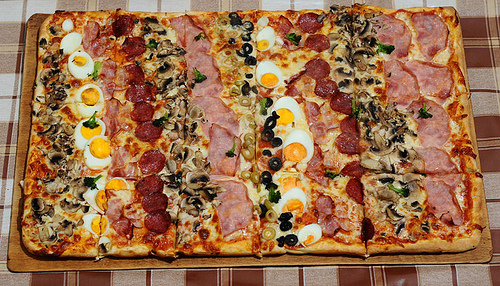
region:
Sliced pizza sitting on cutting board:
[13, 4, 494, 269]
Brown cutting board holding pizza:
[13, 7, 492, 264]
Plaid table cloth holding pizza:
[3, 7, 495, 283]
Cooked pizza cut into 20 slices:
[19, 9, 484, 254]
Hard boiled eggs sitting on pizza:
[68, 52, 112, 244]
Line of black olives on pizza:
[241, 20, 300, 250]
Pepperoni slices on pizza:
[134, 171, 172, 233]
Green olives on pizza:
[236, 132, 262, 184]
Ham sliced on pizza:
[211, 175, 256, 235]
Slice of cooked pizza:
[21, 195, 104, 258]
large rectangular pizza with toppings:
[15, 4, 487, 261]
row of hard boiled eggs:
[53, 16, 131, 237]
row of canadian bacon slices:
[161, 14, 256, 237]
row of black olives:
[227, 11, 304, 251]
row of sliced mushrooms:
[329, 6, 436, 248]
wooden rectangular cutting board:
[6, 4, 496, 270]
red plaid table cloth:
[0, 1, 499, 284]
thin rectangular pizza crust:
[17, 4, 487, 261]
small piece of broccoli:
[80, 110, 101, 130]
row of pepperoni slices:
[295, 6, 382, 248]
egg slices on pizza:
[257, 17, 322, 247]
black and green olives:
[229, 14, 299, 241]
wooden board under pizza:
[5, 229, 498, 272]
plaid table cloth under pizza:
[42, 267, 498, 283]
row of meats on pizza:
[86, 17, 177, 241]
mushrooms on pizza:
[42, 52, 84, 254]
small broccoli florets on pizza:
[82, 107, 104, 129]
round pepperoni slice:
[304, 54, 332, 80]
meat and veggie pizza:
[21, 4, 478, 256]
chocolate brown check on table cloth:
[233, 267, 264, 284]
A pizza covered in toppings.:
[26, 7, 481, 259]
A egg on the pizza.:
[282, 126, 313, 166]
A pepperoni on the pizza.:
[304, 53, 331, 79]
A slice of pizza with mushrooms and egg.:
[20, 176, 107, 256]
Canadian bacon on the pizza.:
[210, 171, 255, 240]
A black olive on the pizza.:
[283, 230, 298, 247]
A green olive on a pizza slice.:
[260, 220, 273, 241]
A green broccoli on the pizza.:
[385, 176, 402, 191]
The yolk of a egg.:
[86, 135, 107, 157]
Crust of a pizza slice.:
[470, 173, 487, 246]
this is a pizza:
[46, 15, 459, 255]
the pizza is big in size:
[38, 17, 451, 244]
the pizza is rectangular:
[45, 15, 465, 255]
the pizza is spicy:
[55, 22, 447, 224]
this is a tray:
[0, 250, 27, 271]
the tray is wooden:
[6, 251, 30, 271]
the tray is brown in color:
[7, 250, 32, 271]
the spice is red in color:
[416, 20, 446, 50]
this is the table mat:
[451, 268, 476, 283]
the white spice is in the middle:
[287, 132, 313, 152]